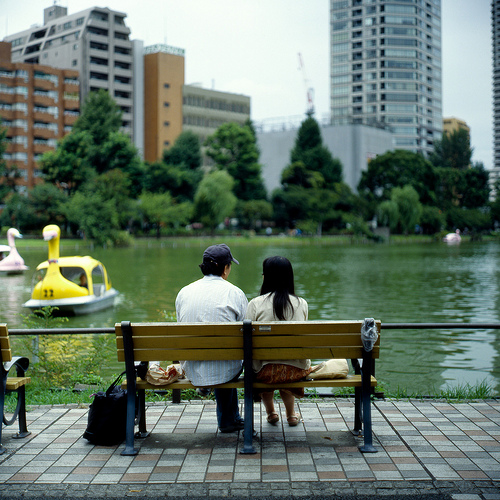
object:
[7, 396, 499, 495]
ground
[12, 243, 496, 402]
water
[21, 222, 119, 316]
boat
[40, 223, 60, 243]
duck head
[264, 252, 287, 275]
hair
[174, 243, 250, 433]
man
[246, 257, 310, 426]
lady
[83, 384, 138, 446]
bag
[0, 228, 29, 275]
boat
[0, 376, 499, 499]
deck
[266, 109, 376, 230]
tree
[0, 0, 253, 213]
building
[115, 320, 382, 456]
benches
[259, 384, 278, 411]
legs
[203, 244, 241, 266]
cap